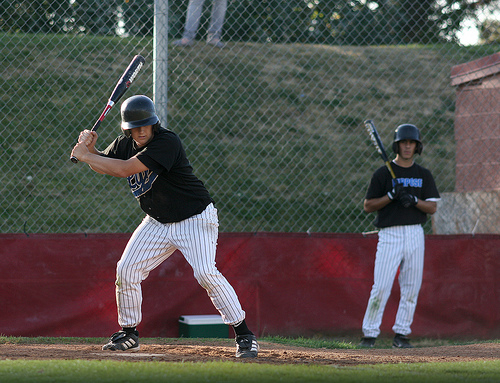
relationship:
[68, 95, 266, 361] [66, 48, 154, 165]
man holds baseball bat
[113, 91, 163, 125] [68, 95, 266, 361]
helmet on man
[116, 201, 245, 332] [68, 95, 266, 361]
jersey pants are on man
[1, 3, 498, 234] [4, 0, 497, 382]
fence around ballpark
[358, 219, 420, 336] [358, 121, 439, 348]
legs of spectator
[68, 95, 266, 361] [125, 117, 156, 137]
man with eyes down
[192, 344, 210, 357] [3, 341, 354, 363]
dirt in batter box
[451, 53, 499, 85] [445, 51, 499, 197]
roof on small building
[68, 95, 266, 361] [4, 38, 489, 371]
man plays baseball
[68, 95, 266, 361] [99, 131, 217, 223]
man wears shirt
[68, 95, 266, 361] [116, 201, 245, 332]
man wears jersey pants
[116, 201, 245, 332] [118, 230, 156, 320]
jersey pants have stripes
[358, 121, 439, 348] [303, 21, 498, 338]
spectator in background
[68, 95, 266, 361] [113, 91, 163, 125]
man wears helmet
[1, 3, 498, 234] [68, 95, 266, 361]
fence behind man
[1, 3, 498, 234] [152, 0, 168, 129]
fence includes pole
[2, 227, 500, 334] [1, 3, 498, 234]
trim for fence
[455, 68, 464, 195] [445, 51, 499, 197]
edge of small building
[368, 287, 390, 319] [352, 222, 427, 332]
grass stain on pants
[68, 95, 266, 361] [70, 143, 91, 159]
man has hand